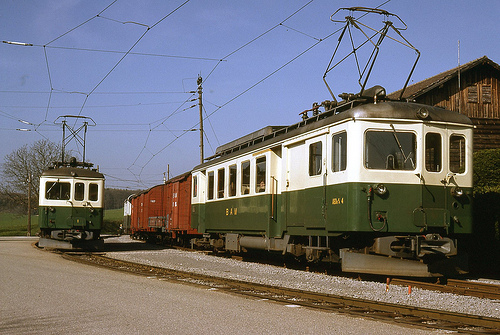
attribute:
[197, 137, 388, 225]
cars — green, passenger, box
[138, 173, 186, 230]
car — passenger, trolley, red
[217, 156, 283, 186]
windows — side, green, foreground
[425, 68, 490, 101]
building — wooden, sitting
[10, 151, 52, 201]
tree — beside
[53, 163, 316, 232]
train — green, white, sitting, riding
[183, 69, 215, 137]
poles — behind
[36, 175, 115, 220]
window — here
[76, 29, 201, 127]
lines — here, over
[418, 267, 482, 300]
track — rusted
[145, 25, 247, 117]
sky — here, blue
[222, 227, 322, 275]
metal — underneath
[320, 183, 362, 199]
number — serial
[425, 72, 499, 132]
buildng — wooden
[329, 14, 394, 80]
conductor — electrical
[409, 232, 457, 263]
connecter — metal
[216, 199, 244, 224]
name — here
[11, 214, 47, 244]
brush — green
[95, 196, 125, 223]
hills — grassy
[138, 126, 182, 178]
clouds — white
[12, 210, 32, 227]
grass — green, here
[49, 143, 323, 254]
trains — seperate, some